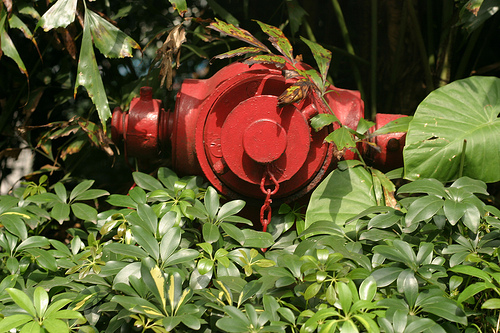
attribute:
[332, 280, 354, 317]
leaf — green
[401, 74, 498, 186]
leaf — large, flat, green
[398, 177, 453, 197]
leaf — green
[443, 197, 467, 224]
leaf — green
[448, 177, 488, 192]
leaf — green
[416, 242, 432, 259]
leaf — green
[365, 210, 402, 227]
leaf — green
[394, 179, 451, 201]
leaf — green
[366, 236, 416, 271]
leaf — green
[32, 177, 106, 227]
leaves — green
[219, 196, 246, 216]
leaf — green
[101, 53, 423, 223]
fire hydrant — red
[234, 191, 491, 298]
leaf — green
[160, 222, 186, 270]
leaf — Bright green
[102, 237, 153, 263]
leaf — Bright green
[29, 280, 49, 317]
leaf — Bright green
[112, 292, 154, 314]
leaf — Bright green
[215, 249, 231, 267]
leaf — Bright green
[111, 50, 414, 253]
fire hydrant — red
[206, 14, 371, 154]
branch — leafy, green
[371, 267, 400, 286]
leaf — green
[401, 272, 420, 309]
leaf — green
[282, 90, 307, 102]
spots — brown